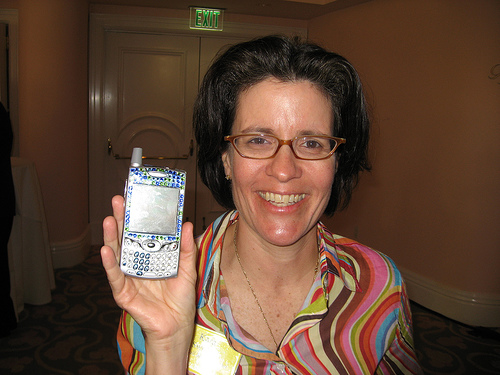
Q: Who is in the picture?
A: A woman.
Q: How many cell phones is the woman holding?
A: One.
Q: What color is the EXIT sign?
A: Green.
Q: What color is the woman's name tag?
A: Yellow.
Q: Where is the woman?
A: In front of doors.